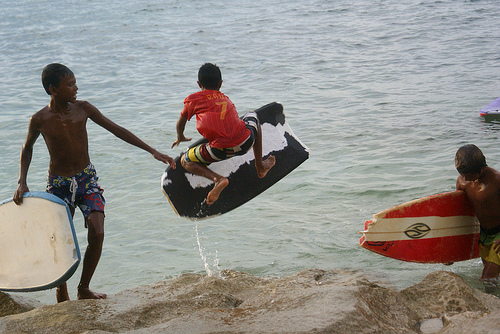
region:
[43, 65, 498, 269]
Kids playing at the beach.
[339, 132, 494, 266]
A boy holding a surfboard.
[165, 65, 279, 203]
A boy on the surfboard.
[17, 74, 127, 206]
The boy is wet.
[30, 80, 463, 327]
Kids standing by the water.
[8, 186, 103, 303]
The surfboard is white.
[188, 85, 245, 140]
The boy is wearing a red shirt.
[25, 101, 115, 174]
The boy is not wearing a shirt.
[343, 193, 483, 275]
The surfboard is red and white.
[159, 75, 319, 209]
The boy standing on the surfboard.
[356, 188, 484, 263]
red surfboard with white stripes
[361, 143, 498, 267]
boy carrying a red surfboard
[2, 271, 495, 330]
rocks along a body of water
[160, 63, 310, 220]
boy jumping in water on a body board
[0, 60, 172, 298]
boy packing a blue and white body board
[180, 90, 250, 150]
boy wearing a red t-shirt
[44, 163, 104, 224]
boy wearing swimming trunks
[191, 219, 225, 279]
water dripping from a boy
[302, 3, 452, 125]
ripples in a body of water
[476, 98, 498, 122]
surfboard floating in the water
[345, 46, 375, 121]
part of a water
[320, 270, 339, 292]
part of a roack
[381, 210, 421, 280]
part of a board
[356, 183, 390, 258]
edge of a board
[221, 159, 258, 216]
part of a board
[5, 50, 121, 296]
a boy holding a surfboard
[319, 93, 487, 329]
a boy holding a surfboard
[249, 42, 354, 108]
the water is green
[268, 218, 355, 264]
the water is green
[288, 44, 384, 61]
the water is green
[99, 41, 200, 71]
the water is green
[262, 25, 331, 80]
the water is green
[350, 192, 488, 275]
part of a red and white surfboard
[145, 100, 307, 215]
a small black and white surfboard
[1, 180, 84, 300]
part of a blue and white surfboard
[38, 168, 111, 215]
a boy's colorful shorts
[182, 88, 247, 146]
a boy's short sleeve shirt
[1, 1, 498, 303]
a large body of water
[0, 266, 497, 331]
an area of land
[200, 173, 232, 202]
a boy's barefoot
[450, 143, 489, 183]
the head of a boy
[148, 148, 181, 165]
the hand of a boy